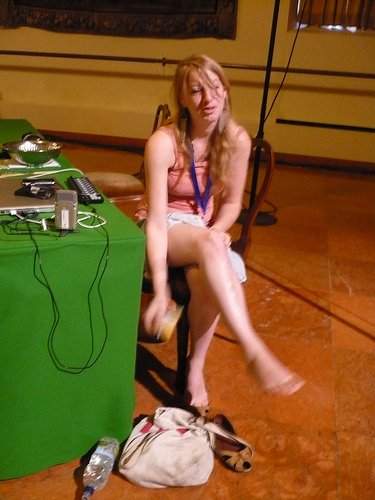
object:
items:
[1, 128, 119, 375]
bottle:
[82, 434, 120, 493]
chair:
[141, 121, 305, 412]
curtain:
[297, 1, 374, 35]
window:
[286, 0, 374, 51]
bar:
[0, 49, 375, 81]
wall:
[2, 0, 373, 158]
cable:
[265, 5, 315, 128]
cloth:
[2, 116, 141, 491]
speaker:
[53, 190, 81, 234]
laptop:
[0, 173, 61, 210]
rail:
[0, 46, 374, 80]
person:
[147, 53, 310, 409]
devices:
[1, 176, 103, 236]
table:
[1, 118, 145, 480]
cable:
[0, 197, 109, 373]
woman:
[135, 52, 306, 407]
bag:
[117, 408, 253, 488]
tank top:
[136, 124, 243, 220]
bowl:
[0, 133, 65, 164]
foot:
[241, 347, 307, 398]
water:
[78, 433, 122, 498]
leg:
[202, 230, 309, 400]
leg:
[178, 269, 220, 406]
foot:
[184, 357, 209, 409]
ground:
[0, 145, 374, 498]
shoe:
[209, 412, 254, 476]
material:
[0, 117, 146, 477]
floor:
[0, 143, 375, 498]